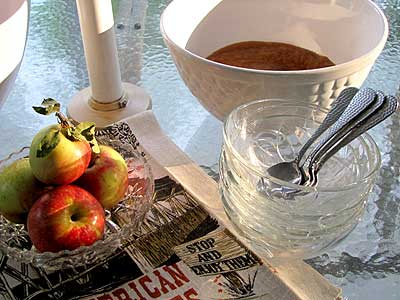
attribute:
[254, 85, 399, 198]
teaspoons — silver, steel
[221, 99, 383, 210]
bowl — glass, clear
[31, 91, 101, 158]
leaves — green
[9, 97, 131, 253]
apples — red, green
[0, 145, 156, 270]
bowl — glass, small, clear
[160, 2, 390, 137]
bowl — white, big, ceramic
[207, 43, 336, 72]
liquid — brown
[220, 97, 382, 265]
bowls — stacked, clear, glass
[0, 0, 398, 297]
table — glass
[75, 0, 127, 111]
pole — white, metal, steel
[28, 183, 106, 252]
apple — red